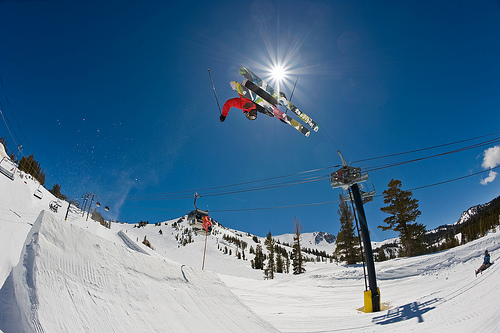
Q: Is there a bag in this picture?
A: No, there are no bags.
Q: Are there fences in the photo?
A: No, there are no fences.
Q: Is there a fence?
A: No, there are no fences.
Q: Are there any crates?
A: No, there are no crates.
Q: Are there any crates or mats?
A: No, there are no crates or mats.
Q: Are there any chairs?
A: Yes, there is a chair.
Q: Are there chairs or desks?
A: Yes, there is a chair.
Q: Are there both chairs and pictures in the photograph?
A: No, there is a chair but no pictures.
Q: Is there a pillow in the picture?
A: No, there are no pillows.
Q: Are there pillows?
A: No, there are no pillows.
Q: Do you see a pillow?
A: No, there are no pillows.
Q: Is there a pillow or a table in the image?
A: No, there are no pillows or tables.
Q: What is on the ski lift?
A: The chair is on the ski lift.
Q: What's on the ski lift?
A: The chair is on the ski lift.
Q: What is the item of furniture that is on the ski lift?
A: The piece of furniture is a chair.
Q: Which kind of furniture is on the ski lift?
A: The piece of furniture is a chair.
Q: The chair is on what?
A: The chair is on the ski lift.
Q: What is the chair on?
A: The chair is on the ski lift.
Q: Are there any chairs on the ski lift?
A: Yes, there is a chair on the ski lift.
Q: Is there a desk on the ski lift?
A: No, there is a chair on the ski lift.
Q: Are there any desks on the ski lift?
A: No, there is a chair on the ski lift.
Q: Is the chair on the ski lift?
A: Yes, the chair is on the ski lift.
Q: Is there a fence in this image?
A: No, there are no fences.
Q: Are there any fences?
A: No, there are no fences.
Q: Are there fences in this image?
A: No, there are no fences.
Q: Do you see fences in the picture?
A: No, there are no fences.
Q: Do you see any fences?
A: No, there are no fences.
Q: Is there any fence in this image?
A: No, there are no fences.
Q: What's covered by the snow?
A: The ground is covered by the snow.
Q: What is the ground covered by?
A: The ground is covered by the snow.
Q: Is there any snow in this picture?
A: Yes, there is snow.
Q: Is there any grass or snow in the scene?
A: Yes, there is snow.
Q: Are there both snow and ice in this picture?
A: No, there is snow but no ice.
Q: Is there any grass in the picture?
A: No, there is no grass.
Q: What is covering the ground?
A: The snow is covering the ground.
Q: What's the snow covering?
A: The snow is covering the ground.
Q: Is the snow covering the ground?
A: Yes, the snow is covering the ground.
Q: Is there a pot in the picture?
A: No, there are no pots.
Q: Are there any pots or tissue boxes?
A: No, there are no pots or tissue boxes.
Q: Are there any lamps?
A: No, there are no lamps.